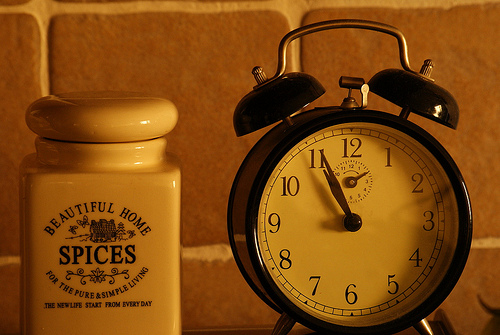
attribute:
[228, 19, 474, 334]
alarm clock — black, white, standing, round, vintage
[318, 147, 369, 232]
hands — black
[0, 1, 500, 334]
tiles — ceramic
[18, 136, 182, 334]
jar — glass, covered, small, white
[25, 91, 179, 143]
lid — rounded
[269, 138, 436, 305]
numbers — black